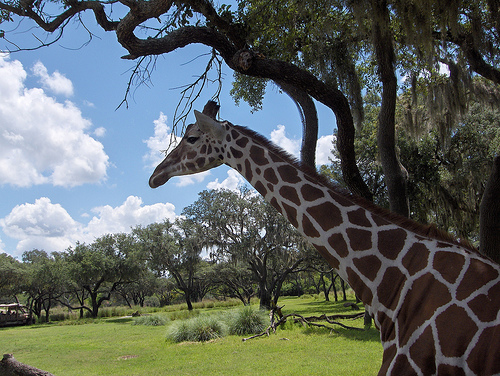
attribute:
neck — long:
[249, 141, 459, 308]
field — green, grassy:
[1, 274, 497, 374]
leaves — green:
[226, 233, 258, 258]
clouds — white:
[2, 50, 106, 238]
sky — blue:
[2, 5, 489, 83]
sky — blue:
[11, 51, 117, 226]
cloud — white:
[26, 60, 80, 100]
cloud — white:
[0, 46, 120, 191]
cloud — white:
[0, 194, 187, 266]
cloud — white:
[140, 109, 212, 186]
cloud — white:
[262, 123, 343, 180]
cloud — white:
[2, 54, 114, 190]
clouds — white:
[1, 54, 143, 228]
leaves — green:
[63, 249, 148, 274]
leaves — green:
[408, 105, 444, 153]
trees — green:
[154, 215, 272, 298]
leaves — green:
[2, 219, 172, 295]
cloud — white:
[271, 127, 350, 174]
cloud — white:
[144, 113, 213, 183]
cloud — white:
[3, 196, 93, 259]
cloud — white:
[145, 106, 213, 182]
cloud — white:
[264, 120, 343, 170]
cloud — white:
[211, 165, 263, 214]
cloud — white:
[147, 110, 208, 180]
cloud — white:
[206, 167, 263, 210]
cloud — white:
[270, 124, 340, 168]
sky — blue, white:
[2, 1, 499, 269]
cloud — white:
[0, 196, 80, 259]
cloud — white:
[206, 167, 262, 217]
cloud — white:
[267, 122, 347, 177]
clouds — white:
[3, 0, 498, 265]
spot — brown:
[244, 140, 273, 166]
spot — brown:
[264, 166, 283, 185]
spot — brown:
[304, 184, 329, 204]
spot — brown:
[342, 205, 372, 230]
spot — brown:
[403, 238, 435, 277]